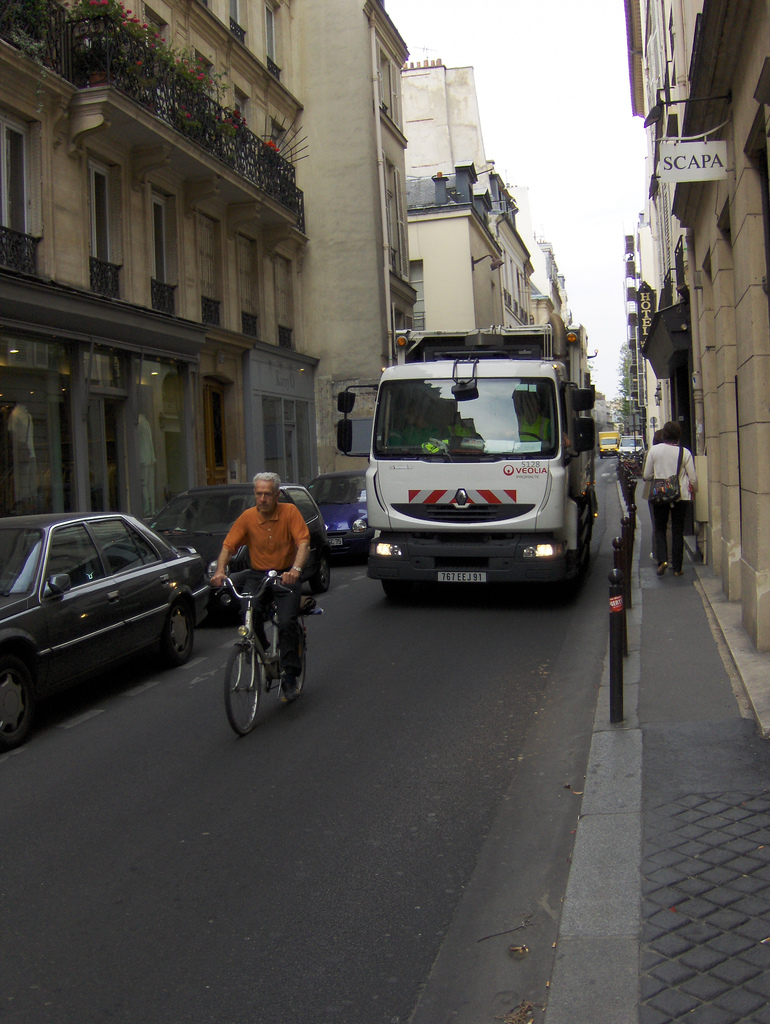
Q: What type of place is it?
A: It is a road.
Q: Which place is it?
A: It is a road.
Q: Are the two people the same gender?
A: No, they are both male and female.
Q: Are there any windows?
A: Yes, there is a window.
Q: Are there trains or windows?
A: Yes, there is a window.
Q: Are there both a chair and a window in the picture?
A: No, there is a window but no chairs.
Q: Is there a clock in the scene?
A: No, there are no clocks.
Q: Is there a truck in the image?
A: Yes, there is a truck.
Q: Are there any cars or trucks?
A: Yes, there is a truck.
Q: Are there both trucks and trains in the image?
A: No, there is a truck but no trains.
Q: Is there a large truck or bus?
A: Yes, there is a large truck.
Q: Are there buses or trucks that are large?
A: Yes, the truck is large.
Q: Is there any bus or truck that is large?
A: Yes, the truck is large.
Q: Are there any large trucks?
A: Yes, there is a large truck.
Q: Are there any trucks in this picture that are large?
A: Yes, there is a truck that is large.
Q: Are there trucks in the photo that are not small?
A: Yes, there is a large truck.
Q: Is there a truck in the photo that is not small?
A: Yes, there is a large truck.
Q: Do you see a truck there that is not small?
A: Yes, there is a large truck.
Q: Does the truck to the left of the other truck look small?
A: No, the truck is large.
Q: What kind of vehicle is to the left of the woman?
A: The vehicle is a truck.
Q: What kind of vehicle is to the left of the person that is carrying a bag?
A: The vehicle is a truck.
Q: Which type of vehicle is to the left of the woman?
A: The vehicle is a truck.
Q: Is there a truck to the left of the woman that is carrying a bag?
A: Yes, there is a truck to the left of the woman.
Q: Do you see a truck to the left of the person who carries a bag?
A: Yes, there is a truck to the left of the woman.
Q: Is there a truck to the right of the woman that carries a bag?
A: No, the truck is to the left of the woman.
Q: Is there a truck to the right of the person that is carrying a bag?
A: No, the truck is to the left of the woman.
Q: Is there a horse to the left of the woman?
A: No, there is a truck to the left of the woman.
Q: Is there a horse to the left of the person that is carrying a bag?
A: No, there is a truck to the left of the woman.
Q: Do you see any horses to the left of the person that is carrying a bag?
A: No, there is a truck to the left of the woman.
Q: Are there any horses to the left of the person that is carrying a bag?
A: No, there is a truck to the left of the woman.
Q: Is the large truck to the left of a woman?
A: Yes, the truck is to the left of a woman.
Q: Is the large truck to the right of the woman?
A: No, the truck is to the left of the woman.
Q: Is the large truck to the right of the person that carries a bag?
A: No, the truck is to the left of the woman.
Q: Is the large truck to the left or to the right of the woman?
A: The truck is to the left of the woman.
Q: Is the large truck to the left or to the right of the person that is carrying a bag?
A: The truck is to the left of the woman.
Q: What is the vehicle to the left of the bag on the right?
A: The vehicle is a truck.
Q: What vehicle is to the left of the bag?
A: The vehicle is a truck.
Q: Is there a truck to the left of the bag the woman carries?
A: Yes, there is a truck to the left of the bag.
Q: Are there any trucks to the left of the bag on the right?
A: Yes, there is a truck to the left of the bag.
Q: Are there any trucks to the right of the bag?
A: No, the truck is to the left of the bag.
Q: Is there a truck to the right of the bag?
A: No, the truck is to the left of the bag.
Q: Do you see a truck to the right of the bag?
A: No, the truck is to the left of the bag.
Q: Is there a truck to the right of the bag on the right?
A: No, the truck is to the left of the bag.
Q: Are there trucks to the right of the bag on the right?
A: No, the truck is to the left of the bag.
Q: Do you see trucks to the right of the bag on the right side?
A: No, the truck is to the left of the bag.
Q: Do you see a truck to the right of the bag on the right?
A: No, the truck is to the left of the bag.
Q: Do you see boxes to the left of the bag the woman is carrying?
A: No, there is a truck to the left of the bag.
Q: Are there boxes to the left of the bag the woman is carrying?
A: No, there is a truck to the left of the bag.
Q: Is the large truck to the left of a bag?
A: Yes, the truck is to the left of a bag.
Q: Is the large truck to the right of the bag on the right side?
A: No, the truck is to the left of the bag.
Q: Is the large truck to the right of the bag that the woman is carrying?
A: No, the truck is to the left of the bag.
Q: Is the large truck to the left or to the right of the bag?
A: The truck is to the left of the bag.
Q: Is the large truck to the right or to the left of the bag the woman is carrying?
A: The truck is to the left of the bag.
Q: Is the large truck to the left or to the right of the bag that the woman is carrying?
A: The truck is to the left of the bag.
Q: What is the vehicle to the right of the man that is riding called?
A: The vehicle is a truck.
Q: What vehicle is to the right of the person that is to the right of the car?
A: The vehicle is a truck.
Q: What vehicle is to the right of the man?
A: The vehicle is a truck.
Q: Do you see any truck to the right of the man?
A: Yes, there is a truck to the right of the man.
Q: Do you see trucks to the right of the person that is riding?
A: Yes, there is a truck to the right of the man.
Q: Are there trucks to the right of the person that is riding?
A: Yes, there is a truck to the right of the man.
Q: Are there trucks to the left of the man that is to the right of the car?
A: No, the truck is to the right of the man.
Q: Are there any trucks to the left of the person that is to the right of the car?
A: No, the truck is to the right of the man.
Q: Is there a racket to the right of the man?
A: No, there is a truck to the right of the man.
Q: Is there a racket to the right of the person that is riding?
A: No, there is a truck to the right of the man.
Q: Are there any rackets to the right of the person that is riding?
A: No, there is a truck to the right of the man.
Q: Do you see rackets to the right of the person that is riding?
A: No, there is a truck to the right of the man.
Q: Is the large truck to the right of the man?
A: Yes, the truck is to the right of the man.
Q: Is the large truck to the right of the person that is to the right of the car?
A: Yes, the truck is to the right of the man.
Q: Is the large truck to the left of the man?
A: No, the truck is to the right of the man.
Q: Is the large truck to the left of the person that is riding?
A: No, the truck is to the right of the man.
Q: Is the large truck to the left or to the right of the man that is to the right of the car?
A: The truck is to the right of the man.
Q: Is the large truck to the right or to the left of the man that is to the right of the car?
A: The truck is to the right of the man.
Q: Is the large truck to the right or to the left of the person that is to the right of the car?
A: The truck is to the right of the man.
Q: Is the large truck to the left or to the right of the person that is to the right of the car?
A: The truck is to the right of the man.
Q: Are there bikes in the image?
A: Yes, there is a bike.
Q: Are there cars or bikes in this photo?
A: Yes, there is a bike.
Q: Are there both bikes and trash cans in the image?
A: No, there is a bike but no trash cans.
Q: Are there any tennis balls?
A: No, there are no tennis balls.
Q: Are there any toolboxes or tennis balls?
A: No, there are no tennis balls or toolboxes.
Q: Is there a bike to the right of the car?
A: Yes, there is a bike to the right of the car.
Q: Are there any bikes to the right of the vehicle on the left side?
A: Yes, there is a bike to the right of the car.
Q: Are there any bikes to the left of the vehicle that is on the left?
A: No, the bike is to the right of the car.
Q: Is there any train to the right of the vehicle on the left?
A: No, there is a bike to the right of the car.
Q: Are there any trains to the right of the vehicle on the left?
A: No, there is a bike to the right of the car.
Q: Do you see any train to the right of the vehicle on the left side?
A: No, there is a bike to the right of the car.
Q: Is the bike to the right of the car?
A: Yes, the bike is to the right of the car.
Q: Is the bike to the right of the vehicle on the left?
A: Yes, the bike is to the right of the car.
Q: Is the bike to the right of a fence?
A: No, the bike is to the right of the car.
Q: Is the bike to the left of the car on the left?
A: No, the bike is to the right of the car.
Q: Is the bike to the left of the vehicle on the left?
A: No, the bike is to the right of the car.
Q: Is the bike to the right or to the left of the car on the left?
A: The bike is to the right of the car.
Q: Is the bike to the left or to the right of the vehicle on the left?
A: The bike is to the right of the car.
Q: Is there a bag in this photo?
A: Yes, there is a bag.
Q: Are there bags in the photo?
A: Yes, there is a bag.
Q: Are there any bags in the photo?
A: Yes, there is a bag.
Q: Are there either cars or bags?
A: Yes, there is a bag.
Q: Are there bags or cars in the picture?
A: Yes, there is a bag.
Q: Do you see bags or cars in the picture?
A: Yes, there is a bag.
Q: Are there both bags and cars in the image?
A: Yes, there are both a bag and a car.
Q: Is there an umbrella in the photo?
A: No, there are no umbrellas.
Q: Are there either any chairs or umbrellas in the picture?
A: No, there are no umbrellas or chairs.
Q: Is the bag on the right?
A: Yes, the bag is on the right of the image.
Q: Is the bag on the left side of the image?
A: No, the bag is on the right of the image.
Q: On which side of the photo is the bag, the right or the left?
A: The bag is on the right of the image.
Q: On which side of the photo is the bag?
A: The bag is on the right of the image.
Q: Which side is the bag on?
A: The bag is on the right of the image.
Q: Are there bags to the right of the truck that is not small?
A: Yes, there is a bag to the right of the truck.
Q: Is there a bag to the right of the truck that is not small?
A: Yes, there is a bag to the right of the truck.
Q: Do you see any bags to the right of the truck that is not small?
A: Yes, there is a bag to the right of the truck.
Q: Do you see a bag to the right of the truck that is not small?
A: Yes, there is a bag to the right of the truck.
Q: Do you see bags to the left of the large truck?
A: No, the bag is to the right of the truck.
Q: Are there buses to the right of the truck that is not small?
A: No, there is a bag to the right of the truck.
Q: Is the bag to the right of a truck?
A: Yes, the bag is to the right of a truck.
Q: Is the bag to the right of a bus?
A: No, the bag is to the right of a truck.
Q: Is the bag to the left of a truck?
A: No, the bag is to the right of a truck.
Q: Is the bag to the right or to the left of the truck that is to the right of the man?
A: The bag is to the right of the truck.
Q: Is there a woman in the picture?
A: Yes, there is a woman.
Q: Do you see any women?
A: Yes, there is a woman.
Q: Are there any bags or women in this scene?
A: Yes, there is a woman.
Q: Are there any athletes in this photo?
A: No, there are no athletes.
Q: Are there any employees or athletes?
A: No, there are no athletes or employees.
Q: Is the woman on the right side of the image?
A: Yes, the woman is on the right of the image.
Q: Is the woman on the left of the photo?
A: No, the woman is on the right of the image.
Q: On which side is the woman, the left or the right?
A: The woman is on the right of the image.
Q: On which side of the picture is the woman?
A: The woman is on the right of the image.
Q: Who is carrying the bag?
A: The woman is carrying the bag.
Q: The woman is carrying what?
A: The woman is carrying a bag.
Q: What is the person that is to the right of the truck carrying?
A: The woman is carrying a bag.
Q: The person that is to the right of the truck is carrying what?
A: The woman is carrying a bag.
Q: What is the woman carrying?
A: The woman is carrying a bag.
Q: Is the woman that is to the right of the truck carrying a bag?
A: Yes, the woman is carrying a bag.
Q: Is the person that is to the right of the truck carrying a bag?
A: Yes, the woman is carrying a bag.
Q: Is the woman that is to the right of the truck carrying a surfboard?
A: No, the woman is carrying a bag.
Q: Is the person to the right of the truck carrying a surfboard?
A: No, the woman is carrying a bag.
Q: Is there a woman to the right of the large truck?
A: Yes, there is a woman to the right of the truck.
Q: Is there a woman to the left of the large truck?
A: No, the woman is to the right of the truck.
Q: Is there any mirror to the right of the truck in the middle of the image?
A: No, there is a woman to the right of the truck.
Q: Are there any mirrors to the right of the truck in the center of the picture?
A: No, there is a woman to the right of the truck.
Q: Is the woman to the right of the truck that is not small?
A: Yes, the woman is to the right of the truck.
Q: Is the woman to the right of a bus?
A: No, the woman is to the right of the truck.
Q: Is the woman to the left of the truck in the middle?
A: No, the woman is to the right of the truck.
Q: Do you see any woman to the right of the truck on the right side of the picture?
A: Yes, there is a woman to the right of the truck.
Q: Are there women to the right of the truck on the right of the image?
A: Yes, there is a woman to the right of the truck.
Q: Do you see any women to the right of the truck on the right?
A: Yes, there is a woman to the right of the truck.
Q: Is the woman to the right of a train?
A: No, the woman is to the right of the truck.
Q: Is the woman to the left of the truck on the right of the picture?
A: No, the woman is to the right of the truck.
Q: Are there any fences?
A: No, there are no fences.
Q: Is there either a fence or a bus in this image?
A: No, there are no fences or buses.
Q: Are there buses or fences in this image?
A: No, there are no fences or buses.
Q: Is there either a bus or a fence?
A: No, there are no fences or buses.